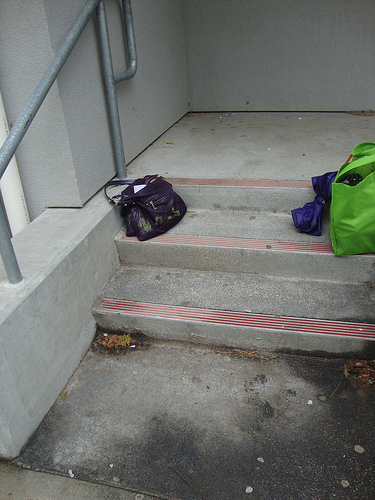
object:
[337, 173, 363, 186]
bag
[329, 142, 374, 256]
item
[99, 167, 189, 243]
purse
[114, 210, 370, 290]
step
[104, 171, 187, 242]
bag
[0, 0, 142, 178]
railings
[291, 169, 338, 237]
blue umbrella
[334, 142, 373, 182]
green handles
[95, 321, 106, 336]
corner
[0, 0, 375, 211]
wall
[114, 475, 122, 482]
spot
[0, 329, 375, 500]
ground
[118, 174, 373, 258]
stairs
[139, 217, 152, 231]
stains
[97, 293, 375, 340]
red metal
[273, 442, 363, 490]
stain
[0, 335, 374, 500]
cement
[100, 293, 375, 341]
marker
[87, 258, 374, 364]
step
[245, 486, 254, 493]
white spot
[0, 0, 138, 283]
metal rail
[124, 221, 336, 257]
stairs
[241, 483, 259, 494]
spot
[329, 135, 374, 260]
tote bag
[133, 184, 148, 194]
paper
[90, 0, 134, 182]
pole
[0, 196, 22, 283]
pole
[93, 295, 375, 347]
treads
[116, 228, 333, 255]
treads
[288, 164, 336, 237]
umbrella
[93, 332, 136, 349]
debris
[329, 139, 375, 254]
bag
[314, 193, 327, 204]
tie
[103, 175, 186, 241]
leather